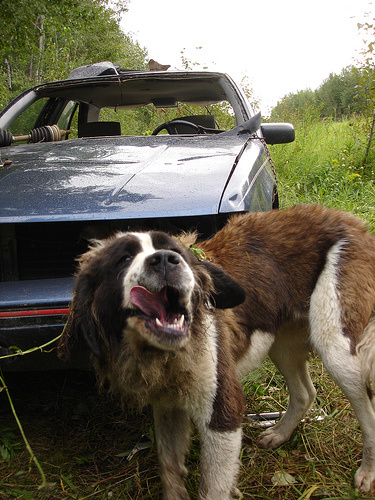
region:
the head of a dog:
[102, 209, 242, 376]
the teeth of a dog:
[127, 287, 218, 347]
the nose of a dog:
[128, 237, 198, 293]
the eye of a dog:
[103, 246, 147, 293]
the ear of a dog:
[61, 255, 108, 371]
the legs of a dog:
[147, 361, 267, 490]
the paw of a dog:
[255, 411, 297, 449]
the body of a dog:
[183, 201, 370, 393]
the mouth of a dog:
[64, 231, 252, 377]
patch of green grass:
[307, 135, 347, 179]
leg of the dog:
[254, 402, 311, 464]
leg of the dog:
[201, 438, 246, 498]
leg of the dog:
[153, 435, 188, 498]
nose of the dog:
[143, 241, 187, 282]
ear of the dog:
[210, 269, 239, 320]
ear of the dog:
[62, 287, 112, 366]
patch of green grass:
[42, 453, 98, 488]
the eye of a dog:
[105, 242, 141, 290]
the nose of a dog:
[137, 239, 195, 287]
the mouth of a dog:
[121, 243, 259, 321]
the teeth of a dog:
[130, 315, 205, 350]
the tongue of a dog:
[131, 254, 180, 340]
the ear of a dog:
[52, 266, 116, 378]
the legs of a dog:
[153, 356, 281, 497]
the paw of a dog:
[256, 416, 302, 458]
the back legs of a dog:
[245, 269, 374, 496]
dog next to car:
[61, 225, 373, 401]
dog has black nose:
[129, 249, 187, 296]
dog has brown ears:
[50, 264, 245, 362]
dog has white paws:
[237, 341, 372, 450]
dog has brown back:
[206, 195, 371, 299]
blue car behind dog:
[26, 78, 254, 313]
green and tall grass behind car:
[273, 119, 373, 215]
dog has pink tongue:
[115, 262, 177, 339]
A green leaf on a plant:
[55, 20, 58, 22]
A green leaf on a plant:
[86, 15, 88, 20]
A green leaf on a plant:
[12, 13, 16, 21]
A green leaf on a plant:
[13, 25, 21, 29]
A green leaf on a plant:
[336, 81, 341, 85]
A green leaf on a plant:
[306, 94, 310, 96]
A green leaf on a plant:
[68, 13, 70, 15]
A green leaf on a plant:
[23, 6, 26, 7]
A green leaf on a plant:
[323, 91, 327, 95]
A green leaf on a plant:
[358, 85, 363, 92]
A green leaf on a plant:
[342, 94, 348, 98]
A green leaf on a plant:
[297, 106, 303, 109]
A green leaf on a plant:
[276, 106, 279, 108]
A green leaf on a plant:
[341, 95, 344, 98]